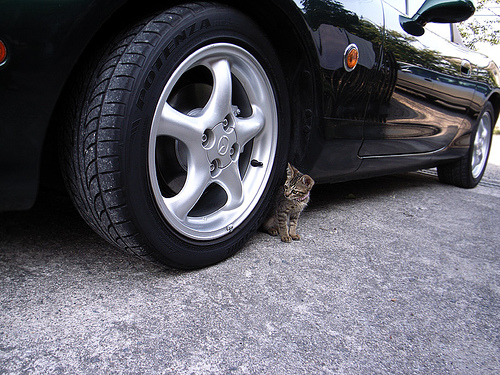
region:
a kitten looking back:
[261, 150, 322, 250]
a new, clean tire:
[70, 3, 278, 281]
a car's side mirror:
[381, 0, 492, 50]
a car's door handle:
[443, 46, 483, 87]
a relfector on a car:
[0, 17, 18, 83]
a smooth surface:
[43, 285, 493, 368]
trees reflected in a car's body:
[383, 30, 496, 86]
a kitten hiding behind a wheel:
[100, 13, 333, 280]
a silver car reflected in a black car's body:
[366, 32, 496, 153]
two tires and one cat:
[77, 3, 498, 261]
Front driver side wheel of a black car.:
[60, 0, 296, 270]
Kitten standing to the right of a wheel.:
[260, 160, 312, 240]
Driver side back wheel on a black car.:
[435, 92, 495, 182]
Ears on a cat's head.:
[285, 160, 310, 185]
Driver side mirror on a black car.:
[400, 0, 472, 30]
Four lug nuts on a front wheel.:
[200, 114, 238, 174]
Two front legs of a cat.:
[276, 206, 300, 243]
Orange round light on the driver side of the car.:
[344, 40, 358, 70]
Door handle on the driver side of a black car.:
[456, 59, 471, 79]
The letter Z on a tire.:
[185, 21, 200, 36]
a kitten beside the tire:
[251, 155, 324, 252]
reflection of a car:
[347, 48, 492, 105]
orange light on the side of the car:
[307, 19, 365, 84]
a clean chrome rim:
[145, 50, 282, 233]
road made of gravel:
[64, 251, 344, 373]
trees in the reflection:
[320, 29, 472, 116]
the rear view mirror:
[390, 0, 477, 40]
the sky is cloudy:
[472, 7, 497, 48]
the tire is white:
[69, 35, 161, 266]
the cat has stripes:
[265, 155, 322, 250]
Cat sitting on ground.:
[262, 156, 312, 247]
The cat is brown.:
[271, 152, 316, 252]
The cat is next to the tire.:
[90, 3, 319, 261]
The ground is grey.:
[0, 169, 498, 368]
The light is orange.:
[340, 41, 357, 71]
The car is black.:
[289, 1, 499, 191]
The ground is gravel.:
[1, 166, 498, 369]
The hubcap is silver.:
[142, 37, 279, 245]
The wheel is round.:
[70, 6, 292, 274]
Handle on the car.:
[455, 57, 474, 77]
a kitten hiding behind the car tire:
[264, 162, 314, 242]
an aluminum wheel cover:
[148, 43, 275, 242]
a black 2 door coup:
[1, 1, 498, 271]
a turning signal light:
[342, 44, 358, 70]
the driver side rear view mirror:
[398, 0, 475, 37]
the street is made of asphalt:
[1, 269, 499, 374]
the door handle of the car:
[460, 61, 471, 76]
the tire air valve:
[251, 158, 263, 168]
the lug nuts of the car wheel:
[200, 133, 208, 143]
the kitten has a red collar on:
[296, 193, 309, 202]